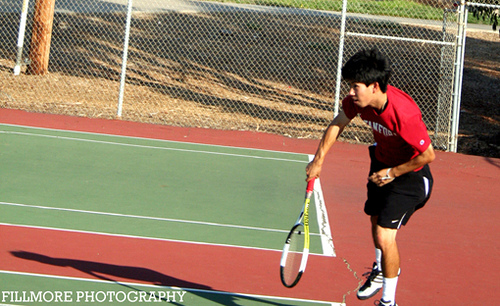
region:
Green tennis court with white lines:
[0, 120, 346, 304]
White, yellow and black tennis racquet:
[280, 194, 311, 289]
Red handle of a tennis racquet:
[302, 178, 314, 193]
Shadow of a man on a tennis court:
[7, 249, 293, 304]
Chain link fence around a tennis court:
[1, 0, 498, 154]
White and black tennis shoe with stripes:
[353, 263, 385, 300]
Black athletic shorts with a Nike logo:
[362, 162, 436, 232]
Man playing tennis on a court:
[301, 45, 437, 304]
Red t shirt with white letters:
[339, 83, 432, 173]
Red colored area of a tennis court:
[0, 105, 498, 304]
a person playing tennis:
[277, 49, 437, 304]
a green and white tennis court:
[29, 150, 304, 223]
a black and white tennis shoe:
[356, 263, 392, 298]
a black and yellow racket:
[281, 156, 318, 288]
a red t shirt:
[343, 93, 433, 161]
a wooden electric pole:
[24, 1, 54, 81]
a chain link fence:
[174, 3, 331, 119]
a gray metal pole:
[449, 1, 471, 153]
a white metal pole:
[11, 1, 31, 74]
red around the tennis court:
[3, 111, 354, 284]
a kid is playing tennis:
[12, 8, 458, 303]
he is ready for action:
[92, 32, 437, 304]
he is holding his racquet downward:
[234, 143, 336, 290]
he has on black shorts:
[348, 156, 450, 242]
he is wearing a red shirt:
[323, 90, 437, 200]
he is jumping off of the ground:
[273, 35, 429, 305]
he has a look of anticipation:
[303, 51, 407, 123]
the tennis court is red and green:
[5, 113, 462, 286]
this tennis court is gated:
[31, 8, 453, 140]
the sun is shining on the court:
[31, 41, 447, 268]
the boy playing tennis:
[279, 46, 434, 304]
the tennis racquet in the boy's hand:
[278, 174, 319, 288]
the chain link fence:
[0, 0, 469, 152]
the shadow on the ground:
[8, 249, 297, 304]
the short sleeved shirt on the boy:
[341, 83, 430, 171]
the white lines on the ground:
[0, 123, 348, 305]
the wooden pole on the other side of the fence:
[27, 0, 55, 73]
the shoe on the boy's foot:
[357, 258, 382, 298]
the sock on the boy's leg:
[381, 275, 398, 302]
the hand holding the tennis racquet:
[303, 160, 321, 182]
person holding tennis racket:
[270, 41, 447, 304]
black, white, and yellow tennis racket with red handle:
[271, 166, 321, 291]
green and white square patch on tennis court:
[2, 114, 336, 272]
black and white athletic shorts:
[360, 148, 436, 233]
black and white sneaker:
[352, 255, 389, 302]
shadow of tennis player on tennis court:
[9, 242, 289, 304]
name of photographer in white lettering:
[2, 284, 192, 303]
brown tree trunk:
[22, 0, 62, 80]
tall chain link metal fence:
[0, 0, 470, 157]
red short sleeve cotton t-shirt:
[340, 80, 432, 170]